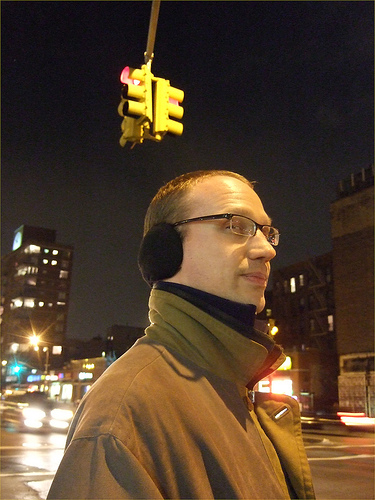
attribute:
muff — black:
[139, 223, 184, 281]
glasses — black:
[169, 214, 281, 248]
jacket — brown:
[45, 336, 313, 498]